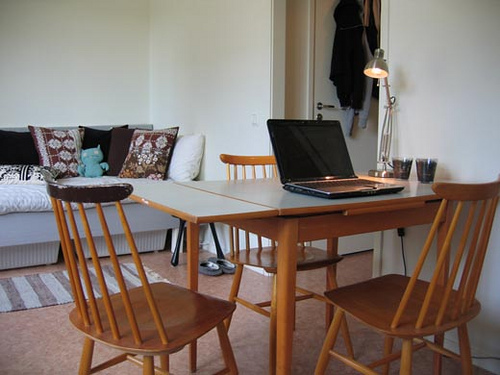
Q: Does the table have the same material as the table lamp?
A: No, the table is made of wood and the table lamp is made of metal.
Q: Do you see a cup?
A: Yes, there is a cup.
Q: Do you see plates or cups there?
A: Yes, there is a cup.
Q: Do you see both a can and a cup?
A: No, there is a cup but no cans.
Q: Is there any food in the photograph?
A: No, there is no food.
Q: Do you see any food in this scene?
A: No, there is no food.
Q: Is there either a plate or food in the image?
A: No, there are no food or plates.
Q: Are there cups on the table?
A: Yes, there is a cup on the table.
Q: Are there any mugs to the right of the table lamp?
A: No, there is a cup to the right of the table lamp.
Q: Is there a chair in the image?
A: Yes, there is a chair.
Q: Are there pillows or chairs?
A: Yes, there is a chair.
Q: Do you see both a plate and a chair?
A: No, there is a chair but no plates.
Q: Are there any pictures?
A: No, there are no pictures.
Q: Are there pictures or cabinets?
A: No, there are no pictures or cabinets.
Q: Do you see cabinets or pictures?
A: No, there are no pictures or cabinets.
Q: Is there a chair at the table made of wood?
A: Yes, there is a chair at the table.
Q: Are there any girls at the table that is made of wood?
A: No, there is a chair at the table.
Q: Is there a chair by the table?
A: Yes, there is a chair by the table.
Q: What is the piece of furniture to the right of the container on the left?
A: The piece of furniture is a chair.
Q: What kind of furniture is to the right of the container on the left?
A: The piece of furniture is a chair.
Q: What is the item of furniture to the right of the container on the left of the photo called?
A: The piece of furniture is a chair.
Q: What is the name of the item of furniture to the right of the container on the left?
A: The piece of furniture is a chair.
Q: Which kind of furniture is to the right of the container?
A: The piece of furniture is a chair.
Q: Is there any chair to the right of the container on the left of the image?
A: Yes, there is a chair to the right of the container.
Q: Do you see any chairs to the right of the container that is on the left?
A: Yes, there is a chair to the right of the container.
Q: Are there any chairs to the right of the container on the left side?
A: Yes, there is a chair to the right of the container.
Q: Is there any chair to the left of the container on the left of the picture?
A: No, the chair is to the right of the container.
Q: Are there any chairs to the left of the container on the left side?
A: No, the chair is to the right of the container.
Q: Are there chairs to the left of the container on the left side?
A: No, the chair is to the right of the container.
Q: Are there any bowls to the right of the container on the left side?
A: No, there is a chair to the right of the container.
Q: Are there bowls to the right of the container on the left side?
A: No, there is a chair to the right of the container.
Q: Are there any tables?
A: Yes, there is a table.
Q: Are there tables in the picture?
A: Yes, there is a table.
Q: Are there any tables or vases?
A: Yes, there is a table.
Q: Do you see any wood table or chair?
A: Yes, there is a wood table.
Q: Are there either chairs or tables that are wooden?
A: Yes, the table is wooden.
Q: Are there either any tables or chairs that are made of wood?
A: Yes, the table is made of wood.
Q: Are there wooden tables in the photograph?
A: Yes, there is a wood table.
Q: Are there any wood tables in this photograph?
A: Yes, there is a wood table.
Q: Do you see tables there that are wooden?
A: Yes, there is a table that is wooden.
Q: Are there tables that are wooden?
A: Yes, there is a table that is wooden.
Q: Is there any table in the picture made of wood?
A: Yes, there is a table that is made of wood.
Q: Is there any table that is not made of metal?
A: Yes, there is a table that is made of wood.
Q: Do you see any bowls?
A: No, there are no bowls.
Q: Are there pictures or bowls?
A: No, there are no bowls or pictures.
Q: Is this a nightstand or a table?
A: This is a table.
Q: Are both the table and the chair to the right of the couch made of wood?
A: Yes, both the table and the chair are made of wood.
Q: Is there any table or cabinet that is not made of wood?
A: No, there is a table but it is made of wood.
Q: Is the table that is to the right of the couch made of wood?
A: Yes, the table is made of wood.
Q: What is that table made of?
A: The table is made of wood.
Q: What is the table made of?
A: The table is made of wood.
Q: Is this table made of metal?
A: No, the table is made of wood.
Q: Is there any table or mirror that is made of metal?
A: No, there is a table but it is made of wood.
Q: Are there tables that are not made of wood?
A: No, there is a table but it is made of wood.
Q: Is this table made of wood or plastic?
A: The table is made of wood.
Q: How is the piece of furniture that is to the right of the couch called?
A: The piece of furniture is a table.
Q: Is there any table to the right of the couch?
A: Yes, there is a table to the right of the couch.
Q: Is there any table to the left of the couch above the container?
A: No, the table is to the right of the couch.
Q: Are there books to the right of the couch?
A: No, there is a table to the right of the couch.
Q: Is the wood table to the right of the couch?
A: Yes, the table is to the right of the couch.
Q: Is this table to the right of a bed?
A: No, the table is to the right of the couch.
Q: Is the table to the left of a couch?
A: No, the table is to the right of a couch.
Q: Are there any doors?
A: Yes, there is a door.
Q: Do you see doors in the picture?
A: Yes, there is a door.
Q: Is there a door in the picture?
A: Yes, there is a door.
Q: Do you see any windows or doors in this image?
A: Yes, there is a door.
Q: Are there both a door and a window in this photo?
A: No, there is a door but no windows.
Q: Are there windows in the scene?
A: No, there are no windows.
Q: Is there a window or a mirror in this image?
A: No, there are no windows or mirrors.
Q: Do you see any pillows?
A: Yes, there is a pillow.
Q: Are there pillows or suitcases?
A: Yes, there is a pillow.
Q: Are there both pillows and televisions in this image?
A: No, there is a pillow but no televisions.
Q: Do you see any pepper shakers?
A: No, there are no pepper shakers.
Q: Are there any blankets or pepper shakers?
A: No, there are no pepper shakers or blankets.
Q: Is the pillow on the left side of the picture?
A: Yes, the pillow is on the left of the image.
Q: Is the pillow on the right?
A: No, the pillow is on the left of the image.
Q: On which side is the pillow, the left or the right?
A: The pillow is on the left of the image.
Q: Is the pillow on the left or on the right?
A: The pillow is on the left of the image.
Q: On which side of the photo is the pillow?
A: The pillow is on the left of the image.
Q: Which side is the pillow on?
A: The pillow is on the left of the image.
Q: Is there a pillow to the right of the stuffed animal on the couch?
A: Yes, there is a pillow to the right of the stuffed animal.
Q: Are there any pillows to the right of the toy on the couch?
A: Yes, there is a pillow to the right of the stuffed animal.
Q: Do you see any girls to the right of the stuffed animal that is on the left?
A: No, there is a pillow to the right of the stuffed animal.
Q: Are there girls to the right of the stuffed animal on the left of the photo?
A: No, there is a pillow to the right of the stuffed animal.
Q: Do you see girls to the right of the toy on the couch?
A: No, there is a pillow to the right of the stuffed animal.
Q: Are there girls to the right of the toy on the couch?
A: No, there is a pillow to the right of the stuffed animal.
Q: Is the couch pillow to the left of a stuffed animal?
A: No, the pillow is to the right of a stuffed animal.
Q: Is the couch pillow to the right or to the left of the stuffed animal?
A: The pillow is to the right of the stuffed animal.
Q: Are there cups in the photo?
A: Yes, there is a cup.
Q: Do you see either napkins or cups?
A: Yes, there is a cup.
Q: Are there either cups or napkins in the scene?
A: Yes, there is a cup.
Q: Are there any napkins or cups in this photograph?
A: Yes, there is a cup.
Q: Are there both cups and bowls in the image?
A: No, there is a cup but no bowls.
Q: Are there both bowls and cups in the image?
A: No, there is a cup but no bowls.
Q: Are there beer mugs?
A: No, there are no beer mugs.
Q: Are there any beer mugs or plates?
A: No, there are no beer mugs or plates.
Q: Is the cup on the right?
A: Yes, the cup is on the right of the image.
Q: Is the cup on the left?
A: No, the cup is on the right of the image.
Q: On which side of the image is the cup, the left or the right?
A: The cup is on the right of the image.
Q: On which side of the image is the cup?
A: The cup is on the right of the image.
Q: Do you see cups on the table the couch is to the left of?
A: Yes, there is a cup on the table.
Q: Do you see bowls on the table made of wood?
A: No, there is a cup on the table.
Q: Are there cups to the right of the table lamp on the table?
A: Yes, there is a cup to the right of the table lamp.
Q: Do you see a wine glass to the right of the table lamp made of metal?
A: No, there is a cup to the right of the table lamp.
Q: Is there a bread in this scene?
A: No, there is no breads.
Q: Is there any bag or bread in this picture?
A: No, there are no breads or bags.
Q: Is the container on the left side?
A: Yes, the container is on the left of the image.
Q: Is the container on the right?
A: No, the container is on the left of the image.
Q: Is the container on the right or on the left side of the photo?
A: The container is on the left of the image.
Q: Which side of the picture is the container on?
A: The container is on the left of the image.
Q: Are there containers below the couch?
A: Yes, there is a container below the couch.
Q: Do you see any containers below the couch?
A: Yes, there is a container below the couch.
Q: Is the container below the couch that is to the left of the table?
A: Yes, the container is below the couch.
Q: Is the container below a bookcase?
A: No, the container is below the couch.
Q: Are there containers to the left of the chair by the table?
A: Yes, there is a container to the left of the chair.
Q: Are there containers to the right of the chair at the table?
A: No, the container is to the left of the chair.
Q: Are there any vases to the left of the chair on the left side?
A: No, there is a container to the left of the chair.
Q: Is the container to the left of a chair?
A: Yes, the container is to the left of a chair.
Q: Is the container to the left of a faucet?
A: No, the container is to the left of a chair.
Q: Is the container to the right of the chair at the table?
A: No, the container is to the left of the chair.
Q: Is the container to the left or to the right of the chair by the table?
A: The container is to the left of the chair.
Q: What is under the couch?
A: The container is under the couch.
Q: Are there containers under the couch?
A: Yes, there is a container under the couch.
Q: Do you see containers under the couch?
A: Yes, there is a container under the couch.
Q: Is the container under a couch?
A: Yes, the container is under a couch.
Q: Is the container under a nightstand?
A: No, the container is under a couch.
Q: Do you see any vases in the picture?
A: No, there are no vases.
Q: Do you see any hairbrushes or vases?
A: No, there are no vases or hairbrushes.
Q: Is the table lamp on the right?
A: Yes, the table lamp is on the right of the image.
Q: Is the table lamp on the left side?
A: No, the table lamp is on the right of the image.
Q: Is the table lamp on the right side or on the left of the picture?
A: The table lamp is on the right of the image.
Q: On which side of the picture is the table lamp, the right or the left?
A: The table lamp is on the right of the image.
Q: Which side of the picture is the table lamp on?
A: The table lamp is on the right of the image.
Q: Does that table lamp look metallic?
A: Yes, the table lamp is metallic.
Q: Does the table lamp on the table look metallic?
A: Yes, the table lamp is metallic.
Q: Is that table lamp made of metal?
A: Yes, the table lamp is made of metal.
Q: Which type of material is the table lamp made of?
A: The table lamp is made of metal.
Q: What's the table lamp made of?
A: The table lamp is made of metal.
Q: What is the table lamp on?
A: The table lamp is on the table.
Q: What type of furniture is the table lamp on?
A: The table lamp is on the table.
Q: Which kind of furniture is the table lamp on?
A: The table lamp is on the table.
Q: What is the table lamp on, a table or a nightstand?
A: The table lamp is on a table.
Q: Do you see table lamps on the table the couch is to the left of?
A: Yes, there is a table lamp on the table.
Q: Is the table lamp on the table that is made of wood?
A: Yes, the table lamp is on the table.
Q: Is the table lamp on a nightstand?
A: No, the table lamp is on the table.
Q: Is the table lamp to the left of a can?
A: No, the table lamp is to the left of the cup.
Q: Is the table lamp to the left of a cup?
A: Yes, the table lamp is to the left of a cup.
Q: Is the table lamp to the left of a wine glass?
A: No, the table lamp is to the left of a cup.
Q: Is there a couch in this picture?
A: Yes, there is a couch.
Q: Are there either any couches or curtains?
A: Yes, there is a couch.